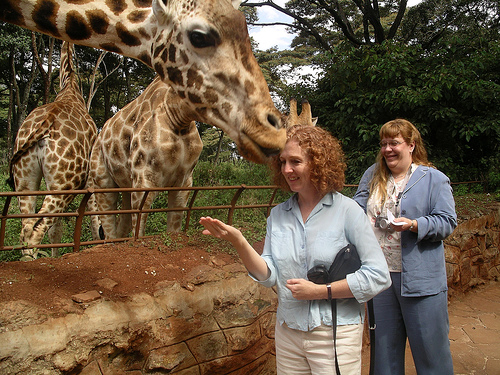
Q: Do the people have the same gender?
A: Yes, all the people are female.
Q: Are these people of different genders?
A: No, all the people are female.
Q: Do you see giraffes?
A: Yes, there is a giraffe.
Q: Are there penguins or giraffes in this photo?
A: Yes, there is a giraffe.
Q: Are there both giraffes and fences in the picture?
A: Yes, there are both a giraffe and a fence.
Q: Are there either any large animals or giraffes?
A: Yes, there is a large giraffe.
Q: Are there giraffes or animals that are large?
A: Yes, the giraffe is large.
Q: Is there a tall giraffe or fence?
A: Yes, there is a tall giraffe.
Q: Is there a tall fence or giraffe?
A: Yes, there is a tall giraffe.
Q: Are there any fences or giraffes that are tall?
A: Yes, the giraffe is tall.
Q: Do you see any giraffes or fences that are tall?
A: Yes, the giraffe is tall.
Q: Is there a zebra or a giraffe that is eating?
A: Yes, the giraffe is eating.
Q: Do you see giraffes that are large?
A: Yes, there is a large giraffe.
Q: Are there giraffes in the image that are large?
A: Yes, there is a giraffe that is large.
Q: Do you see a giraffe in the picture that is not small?
A: Yes, there is a large giraffe.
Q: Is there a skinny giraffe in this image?
A: Yes, there is a skinny giraffe.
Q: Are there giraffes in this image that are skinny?
A: Yes, there is a giraffe that is skinny.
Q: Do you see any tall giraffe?
A: Yes, there is a tall giraffe.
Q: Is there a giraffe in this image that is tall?
A: Yes, there is a giraffe that is tall.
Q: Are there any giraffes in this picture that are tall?
A: Yes, there is a giraffe that is tall.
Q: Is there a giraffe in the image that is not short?
A: Yes, there is a tall giraffe.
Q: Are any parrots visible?
A: No, there are no parrots.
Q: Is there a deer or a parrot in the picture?
A: No, there are no parrots or deer.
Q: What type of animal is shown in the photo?
A: The animal is a giraffe.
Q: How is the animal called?
A: The animal is a giraffe.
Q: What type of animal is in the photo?
A: The animal is a giraffe.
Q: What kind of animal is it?
A: The animal is a giraffe.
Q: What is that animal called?
A: That is a giraffe.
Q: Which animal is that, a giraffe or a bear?
A: That is a giraffe.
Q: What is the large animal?
A: The animal is a giraffe.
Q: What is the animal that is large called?
A: The animal is a giraffe.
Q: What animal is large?
A: The animal is a giraffe.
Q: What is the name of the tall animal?
A: The animal is a giraffe.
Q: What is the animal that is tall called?
A: The animal is a giraffe.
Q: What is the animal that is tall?
A: The animal is a giraffe.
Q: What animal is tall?
A: The animal is a giraffe.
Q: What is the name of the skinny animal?
A: The animal is a giraffe.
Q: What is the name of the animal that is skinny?
A: The animal is a giraffe.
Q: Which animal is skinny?
A: The animal is a giraffe.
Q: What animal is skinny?
A: The animal is a giraffe.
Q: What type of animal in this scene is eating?
A: The animal is a giraffe.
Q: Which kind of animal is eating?
A: The animal is a giraffe.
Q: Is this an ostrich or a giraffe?
A: This is a giraffe.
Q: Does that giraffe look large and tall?
A: Yes, the giraffe is large and tall.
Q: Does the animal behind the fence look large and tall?
A: Yes, the giraffe is large and tall.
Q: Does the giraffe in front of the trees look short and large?
A: No, the giraffe is large but tall.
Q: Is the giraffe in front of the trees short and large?
A: No, the giraffe is large but tall.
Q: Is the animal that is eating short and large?
A: No, the giraffe is large but tall.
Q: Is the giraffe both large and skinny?
A: Yes, the giraffe is large and skinny.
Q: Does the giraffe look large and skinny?
A: Yes, the giraffe is large and skinny.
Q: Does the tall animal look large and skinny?
A: Yes, the giraffe is large and skinny.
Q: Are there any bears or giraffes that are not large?
A: No, there is a giraffe but it is large.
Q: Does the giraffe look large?
A: Yes, the giraffe is large.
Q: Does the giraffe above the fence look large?
A: Yes, the giraffe is large.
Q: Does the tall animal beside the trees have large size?
A: Yes, the giraffe is large.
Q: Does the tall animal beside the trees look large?
A: Yes, the giraffe is large.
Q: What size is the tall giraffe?
A: The giraffe is large.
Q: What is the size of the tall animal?
A: The giraffe is large.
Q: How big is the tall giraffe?
A: The giraffe is large.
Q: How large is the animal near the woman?
A: The giraffe is large.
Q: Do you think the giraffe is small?
A: No, the giraffe is large.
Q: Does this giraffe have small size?
A: No, the giraffe is large.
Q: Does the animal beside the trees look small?
A: No, the giraffe is large.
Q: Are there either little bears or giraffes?
A: No, there is a giraffe but it is large.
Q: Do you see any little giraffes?
A: No, there is a giraffe but it is large.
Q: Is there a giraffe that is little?
A: No, there is a giraffe but it is large.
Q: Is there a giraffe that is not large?
A: No, there is a giraffe but it is large.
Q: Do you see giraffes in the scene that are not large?
A: No, there is a giraffe but it is large.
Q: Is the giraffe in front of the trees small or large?
A: The giraffe is large.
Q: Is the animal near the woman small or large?
A: The giraffe is large.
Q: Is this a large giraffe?
A: Yes, this is a large giraffe.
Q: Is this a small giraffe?
A: No, this is a large giraffe.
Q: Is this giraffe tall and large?
A: Yes, the giraffe is tall and large.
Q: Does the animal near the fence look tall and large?
A: Yes, the giraffe is tall and large.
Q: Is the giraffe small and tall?
A: No, the giraffe is tall but large.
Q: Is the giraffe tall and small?
A: No, the giraffe is tall but large.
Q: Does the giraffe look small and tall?
A: No, the giraffe is tall but large.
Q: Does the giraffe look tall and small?
A: No, the giraffe is tall but large.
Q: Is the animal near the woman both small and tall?
A: No, the giraffe is tall but large.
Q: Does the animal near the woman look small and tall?
A: No, the giraffe is tall but large.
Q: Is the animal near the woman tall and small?
A: No, the giraffe is tall but large.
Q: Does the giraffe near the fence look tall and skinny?
A: Yes, the giraffe is tall and skinny.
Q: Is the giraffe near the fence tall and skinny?
A: Yes, the giraffe is tall and skinny.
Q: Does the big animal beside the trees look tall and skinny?
A: Yes, the giraffe is tall and skinny.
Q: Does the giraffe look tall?
A: Yes, the giraffe is tall.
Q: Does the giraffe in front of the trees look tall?
A: Yes, the giraffe is tall.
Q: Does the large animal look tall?
A: Yes, the giraffe is tall.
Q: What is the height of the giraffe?
A: The giraffe is tall.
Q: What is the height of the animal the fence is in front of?
A: The giraffe is tall.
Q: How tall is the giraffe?
A: The giraffe is tall.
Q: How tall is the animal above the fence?
A: The giraffe is tall.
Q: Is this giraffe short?
A: No, the giraffe is tall.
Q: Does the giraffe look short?
A: No, the giraffe is tall.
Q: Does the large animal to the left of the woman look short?
A: No, the giraffe is tall.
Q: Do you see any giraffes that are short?
A: No, there is a giraffe but it is tall.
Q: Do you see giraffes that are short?
A: No, there is a giraffe but it is tall.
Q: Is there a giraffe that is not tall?
A: No, there is a giraffe but it is tall.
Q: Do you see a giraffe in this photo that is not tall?
A: No, there is a giraffe but it is tall.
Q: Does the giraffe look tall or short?
A: The giraffe is tall.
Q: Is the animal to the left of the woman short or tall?
A: The giraffe is tall.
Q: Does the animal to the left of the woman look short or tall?
A: The giraffe is tall.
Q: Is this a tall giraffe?
A: Yes, this is a tall giraffe.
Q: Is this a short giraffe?
A: No, this is a tall giraffe.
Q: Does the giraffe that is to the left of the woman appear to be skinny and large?
A: Yes, the giraffe is skinny and large.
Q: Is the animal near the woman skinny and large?
A: Yes, the giraffe is skinny and large.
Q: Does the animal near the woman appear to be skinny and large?
A: Yes, the giraffe is skinny and large.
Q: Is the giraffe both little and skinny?
A: No, the giraffe is skinny but large.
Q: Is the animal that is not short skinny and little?
A: No, the giraffe is skinny but large.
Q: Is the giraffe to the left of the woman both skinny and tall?
A: Yes, the giraffe is skinny and tall.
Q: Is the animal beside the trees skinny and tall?
A: Yes, the giraffe is skinny and tall.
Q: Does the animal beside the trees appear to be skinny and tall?
A: Yes, the giraffe is skinny and tall.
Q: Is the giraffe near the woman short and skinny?
A: No, the giraffe is skinny but tall.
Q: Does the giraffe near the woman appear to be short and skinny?
A: No, the giraffe is skinny but tall.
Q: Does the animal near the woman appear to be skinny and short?
A: No, the giraffe is skinny but tall.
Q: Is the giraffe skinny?
A: Yes, the giraffe is skinny.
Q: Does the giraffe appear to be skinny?
A: Yes, the giraffe is skinny.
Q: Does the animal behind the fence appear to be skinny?
A: Yes, the giraffe is skinny.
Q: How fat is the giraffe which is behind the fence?
A: The giraffe is skinny.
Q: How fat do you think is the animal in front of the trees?
A: The giraffe is skinny.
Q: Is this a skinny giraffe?
A: Yes, this is a skinny giraffe.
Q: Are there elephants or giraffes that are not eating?
A: No, there is a giraffe but it is eating.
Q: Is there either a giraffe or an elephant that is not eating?
A: No, there is a giraffe but it is eating.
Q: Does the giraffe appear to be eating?
A: Yes, the giraffe is eating.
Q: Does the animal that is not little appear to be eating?
A: Yes, the giraffe is eating.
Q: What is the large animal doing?
A: The giraffe is eating.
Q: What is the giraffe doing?
A: The giraffe is eating.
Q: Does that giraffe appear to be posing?
A: No, the giraffe is eating.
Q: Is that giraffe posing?
A: No, the giraffe is eating.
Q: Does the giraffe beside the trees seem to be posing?
A: No, the giraffe is eating.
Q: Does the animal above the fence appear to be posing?
A: No, the giraffe is eating.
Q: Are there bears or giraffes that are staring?
A: No, there is a giraffe but it is eating.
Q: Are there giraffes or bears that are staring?
A: No, there is a giraffe but it is eating.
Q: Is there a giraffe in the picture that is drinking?
A: No, there is a giraffe but it is eating.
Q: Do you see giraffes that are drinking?
A: No, there is a giraffe but it is eating.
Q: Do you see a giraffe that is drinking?
A: No, there is a giraffe but it is eating.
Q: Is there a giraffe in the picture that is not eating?
A: No, there is a giraffe but it is eating.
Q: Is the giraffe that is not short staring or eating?
A: The giraffe is eating.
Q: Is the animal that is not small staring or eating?
A: The giraffe is eating.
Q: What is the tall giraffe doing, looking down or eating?
A: The giraffe is eating.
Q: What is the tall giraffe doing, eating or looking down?
A: The giraffe is eating.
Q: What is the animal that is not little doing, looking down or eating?
A: The giraffe is eating.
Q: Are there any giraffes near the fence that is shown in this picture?
A: Yes, there is a giraffe near the fence.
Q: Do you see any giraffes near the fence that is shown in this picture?
A: Yes, there is a giraffe near the fence.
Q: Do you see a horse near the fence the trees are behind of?
A: No, there is a giraffe near the fence.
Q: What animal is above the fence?
A: The animal is a giraffe.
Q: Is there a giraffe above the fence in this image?
A: Yes, there is a giraffe above the fence.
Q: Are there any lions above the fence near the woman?
A: No, there is a giraffe above the fence.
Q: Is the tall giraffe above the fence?
A: Yes, the giraffe is above the fence.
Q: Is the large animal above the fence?
A: Yes, the giraffe is above the fence.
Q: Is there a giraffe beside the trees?
A: Yes, there is a giraffe beside the trees.